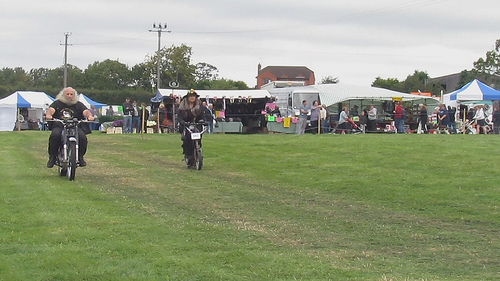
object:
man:
[43, 83, 98, 168]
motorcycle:
[39, 116, 99, 180]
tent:
[0, 91, 53, 131]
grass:
[0, 130, 499, 279]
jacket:
[175, 101, 211, 128]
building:
[255, 63, 315, 90]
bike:
[47, 113, 98, 181]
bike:
[177, 121, 215, 170]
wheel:
[67, 141, 78, 181]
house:
[255, 63, 315, 90]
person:
[42, 87, 98, 168]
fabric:
[275, 117, 299, 128]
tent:
[75, 93, 107, 108]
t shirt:
[49, 100, 89, 125]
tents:
[203, 81, 433, 110]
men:
[120, 98, 140, 135]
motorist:
[45, 85, 99, 168]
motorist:
[177, 90, 216, 170]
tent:
[442, 79, 500, 102]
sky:
[0, 2, 499, 62]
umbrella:
[439, 78, 500, 106]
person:
[175, 89, 213, 162]